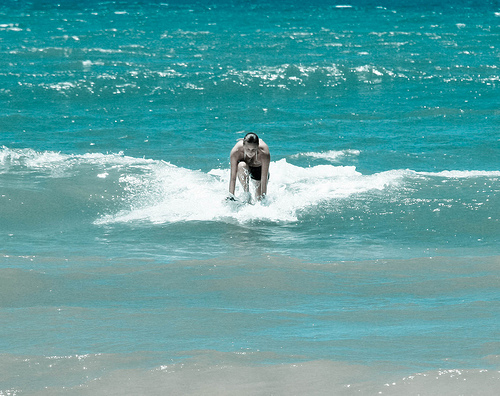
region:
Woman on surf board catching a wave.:
[225, 132, 276, 205]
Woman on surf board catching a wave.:
[226, 136, 272, 207]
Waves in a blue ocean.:
[53, 22, 299, 106]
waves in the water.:
[295, 249, 480, 353]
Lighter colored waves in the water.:
[26, 352, 114, 387]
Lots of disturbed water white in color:
[282, 154, 398, 229]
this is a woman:
[217, 131, 275, 215]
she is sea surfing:
[217, 126, 275, 214]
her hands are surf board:
[219, 181, 275, 209]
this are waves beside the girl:
[140, 171, 217, 223]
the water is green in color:
[305, 89, 490, 161]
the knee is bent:
[234, 161, 253, 203]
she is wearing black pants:
[252, 169, 259, 177]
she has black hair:
[245, 133, 258, 140]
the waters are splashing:
[215, 182, 248, 216]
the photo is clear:
[4, 2, 499, 394]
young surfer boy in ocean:
[215, 122, 317, 221]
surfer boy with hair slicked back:
[218, 126, 283, 227]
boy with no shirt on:
[209, 126, 286, 214]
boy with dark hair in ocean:
[164, 126, 321, 238]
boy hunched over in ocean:
[203, 126, 290, 206]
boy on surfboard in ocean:
[214, 127, 298, 229]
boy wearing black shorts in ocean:
[196, 129, 308, 225]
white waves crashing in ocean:
[296, 161, 386, 244]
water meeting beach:
[350, 355, 425, 386]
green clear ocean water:
[211, 261, 343, 299]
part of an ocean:
[220, 25, 410, 113]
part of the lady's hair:
[246, 128, 258, 141]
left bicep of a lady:
[261, 160, 269, 187]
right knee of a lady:
[236, 165, 250, 180]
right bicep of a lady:
[227, 152, 237, 192]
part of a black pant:
[251, 167, 259, 178]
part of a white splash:
[188, 186, 243, 218]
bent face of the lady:
[241, 130, 259, 162]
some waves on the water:
[248, 57, 345, 119]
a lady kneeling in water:
[213, 125, 300, 242]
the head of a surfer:
[242, 136, 259, 158]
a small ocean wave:
[55, 62, 417, 82]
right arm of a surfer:
[230, 151, 236, 199]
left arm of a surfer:
[262, 148, 268, 203]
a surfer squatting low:
[228, 127, 273, 208]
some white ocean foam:
[135, 164, 220, 222]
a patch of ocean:
[368, 279, 484, 354]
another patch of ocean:
[9, 248, 185, 354]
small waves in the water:
[188, 30, 482, 57]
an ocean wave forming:
[368, 170, 485, 247]